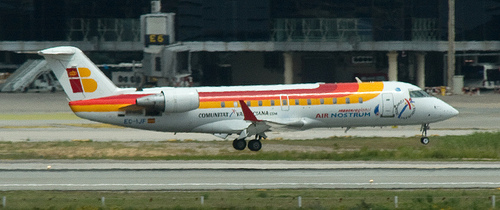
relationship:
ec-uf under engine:
[120, 115, 148, 129] [136, 89, 203, 115]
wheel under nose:
[419, 136, 431, 146] [420, 97, 466, 124]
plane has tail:
[33, 40, 463, 147] [36, 46, 118, 103]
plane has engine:
[33, 40, 463, 147] [136, 89, 203, 115]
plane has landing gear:
[33, 40, 463, 147] [232, 134, 264, 154]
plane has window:
[33, 40, 463, 147] [345, 96, 351, 106]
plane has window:
[33, 40, 463, 147] [402, 87, 434, 100]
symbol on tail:
[65, 64, 99, 98] [36, 46, 118, 103]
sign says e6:
[135, 8, 181, 81] [140, 32, 170, 46]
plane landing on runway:
[33, 40, 463, 147] [5, 151, 500, 194]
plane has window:
[33, 40, 463, 147] [294, 96, 303, 107]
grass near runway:
[2, 131, 499, 162] [5, 151, 500, 194]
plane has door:
[33, 40, 463, 147] [383, 93, 398, 119]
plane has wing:
[33, 40, 463, 147] [192, 117, 316, 139]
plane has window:
[33, 40, 463, 147] [219, 99, 227, 110]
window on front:
[402, 87, 434, 100] [394, 80, 460, 129]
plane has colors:
[33, 40, 463, 147] [69, 66, 385, 115]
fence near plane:
[4, 195, 500, 209] [33, 40, 463, 147]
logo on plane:
[329, 112, 374, 120] [33, 40, 463, 147]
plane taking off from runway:
[33, 40, 463, 147] [5, 151, 500, 194]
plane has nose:
[33, 40, 463, 147] [420, 97, 466, 124]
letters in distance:
[146, 35, 167, 49] [12, 8, 500, 101]